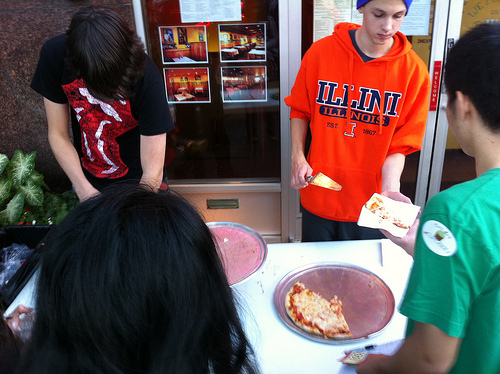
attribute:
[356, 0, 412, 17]
hat — blue 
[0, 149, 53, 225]
plant — green 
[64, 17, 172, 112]
hair — black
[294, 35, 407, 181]
hoodie — Orange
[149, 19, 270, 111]
pictures — colorful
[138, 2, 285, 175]
window — clear, glass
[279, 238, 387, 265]
table — white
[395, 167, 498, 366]
shirt — green, tee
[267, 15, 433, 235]
sweater — orange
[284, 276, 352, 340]
sauce — orange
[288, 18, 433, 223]
sweatshirt — orange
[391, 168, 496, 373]
tshirt — green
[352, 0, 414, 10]
hat — blue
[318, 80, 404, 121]
letters — blue